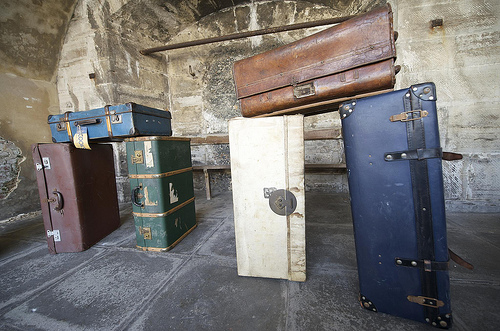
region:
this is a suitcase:
[353, 78, 443, 301]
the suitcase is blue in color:
[358, 180, 420, 238]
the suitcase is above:
[254, 15, 384, 112]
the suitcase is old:
[234, 144, 296, 253]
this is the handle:
[122, 184, 144, 211]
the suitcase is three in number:
[30, 97, 177, 266]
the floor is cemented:
[157, 264, 225, 327]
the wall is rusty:
[56, 8, 135, 90]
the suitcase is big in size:
[353, 80, 441, 302]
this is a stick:
[176, 24, 213, 62]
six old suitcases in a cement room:
[26, 7, 483, 326]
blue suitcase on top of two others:
[40, 104, 167, 152]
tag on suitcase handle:
[68, 127, 95, 154]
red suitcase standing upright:
[26, 138, 121, 259]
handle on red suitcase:
[45, 184, 70, 218]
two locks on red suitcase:
[32, 153, 65, 247]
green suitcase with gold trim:
[118, 132, 205, 257]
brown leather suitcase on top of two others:
[220, 3, 410, 148]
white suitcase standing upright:
[216, 108, 318, 296]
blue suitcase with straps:
[331, 75, 471, 329]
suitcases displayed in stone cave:
[18, 10, 466, 321]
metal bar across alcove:
[91, 5, 403, 70]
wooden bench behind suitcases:
[145, 120, 357, 205]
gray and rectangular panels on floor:
[17, 190, 354, 325]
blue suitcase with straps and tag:
[37, 101, 172, 151]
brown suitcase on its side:
[17, 141, 117, 261]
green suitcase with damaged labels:
[116, 130, 206, 251]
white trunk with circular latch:
[225, 102, 315, 287]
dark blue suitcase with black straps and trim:
[326, 85, 466, 322]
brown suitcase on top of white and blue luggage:
[217, 7, 445, 164]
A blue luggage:
[348, 63, 450, 322]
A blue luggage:
[319, 27, 368, 313]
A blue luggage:
[356, 97, 431, 207]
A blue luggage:
[360, 120, 394, 316]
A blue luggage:
[320, 113, 411, 322]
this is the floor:
[79, 264, 156, 301]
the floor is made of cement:
[76, 282, 178, 305]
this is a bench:
[196, 136, 222, 189]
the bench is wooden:
[192, 140, 224, 189]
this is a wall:
[170, 71, 204, 119]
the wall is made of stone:
[430, 37, 474, 64]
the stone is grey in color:
[445, 64, 470, 100]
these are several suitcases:
[21, 7, 469, 326]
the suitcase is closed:
[338, 31, 380, 73]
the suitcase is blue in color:
[383, 175, 402, 214]